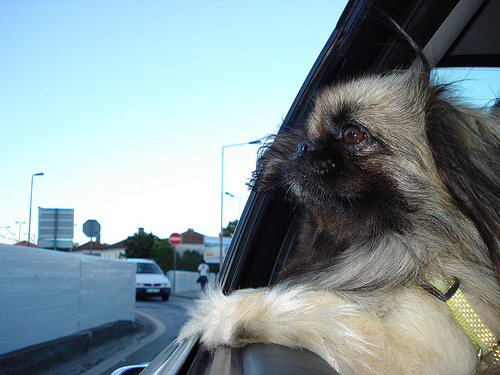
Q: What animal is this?
A: Dog.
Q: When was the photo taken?
A: Daytime.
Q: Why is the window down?
A: So the dog can get fresh air.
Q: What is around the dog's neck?
A: A leash.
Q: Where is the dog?
A: In the car.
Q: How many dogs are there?
A: One.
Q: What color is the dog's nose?
A: Black.